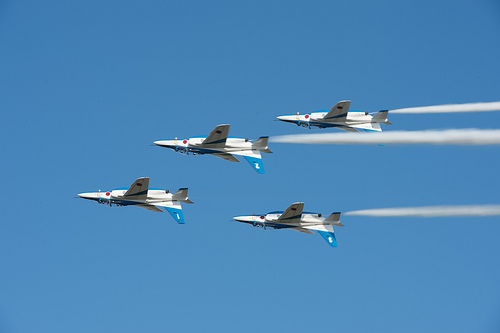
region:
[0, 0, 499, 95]
A clear blue sky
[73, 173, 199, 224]
An airplane flying in the front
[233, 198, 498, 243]
An airplane flying with a trail of white smoke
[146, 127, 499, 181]
A middle airplane flying with a trail of white smoke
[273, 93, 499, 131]
The top airplane flying with a trail of white smoke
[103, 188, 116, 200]
A red dot near the front of the plane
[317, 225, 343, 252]
A blue tail of the plane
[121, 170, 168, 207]
The wing of the leading plane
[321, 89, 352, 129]
The wing of the last plane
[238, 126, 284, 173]
The end of the middle plane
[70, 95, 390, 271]
Four jets flying in the air.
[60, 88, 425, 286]
Four airplanes flying in an airshow.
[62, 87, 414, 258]
Jets flying in the air.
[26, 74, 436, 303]
Jets flying in the blue sky.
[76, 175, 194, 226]
Blue and white jet flying in front of the other jets.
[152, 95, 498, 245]
Three airplanes releasing exhaustion.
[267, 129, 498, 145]
Exhaustion coming from an airplane.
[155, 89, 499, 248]
Three airplanes releasing white exhaust.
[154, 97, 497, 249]
Three white and blue jets flying in the air releasing exhaustion.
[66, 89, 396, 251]
Four white and blue jets flying in an airshow.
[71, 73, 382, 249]
Planes flying upside down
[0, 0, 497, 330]
sky is clear and blue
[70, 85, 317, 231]
planes have a red mark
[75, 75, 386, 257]
planes have blue tail fin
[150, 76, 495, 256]
Most of planes leaving jetstream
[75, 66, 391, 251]
Planes are at airshow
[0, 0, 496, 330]
The scene is daytime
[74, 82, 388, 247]
The planes are white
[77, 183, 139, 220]
Cockpit holds two people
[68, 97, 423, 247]
There are four people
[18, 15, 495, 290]
four jets flying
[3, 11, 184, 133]
clear blue sky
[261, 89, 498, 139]
white fighter jet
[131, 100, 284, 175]
white fighter jet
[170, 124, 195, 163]
red dot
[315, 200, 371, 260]
tail end of fighter jet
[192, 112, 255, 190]
wings of a fighter jet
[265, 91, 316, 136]
front of a fighter jet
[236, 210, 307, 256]
landing gear of a fighter jet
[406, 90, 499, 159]
sky and jet trail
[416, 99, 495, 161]
smoke billowing from the planes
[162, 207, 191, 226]
a blue tail fin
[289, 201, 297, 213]
a circle painted on the wing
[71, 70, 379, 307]
planes flying in formation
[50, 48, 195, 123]
a clear blue sky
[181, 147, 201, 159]
black rubber airplane wheels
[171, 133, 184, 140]
the cockpit of the plane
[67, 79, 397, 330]
fighter jets on a mission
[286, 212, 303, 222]
a blue stripe on the wing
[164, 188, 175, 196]
the engine of the plane